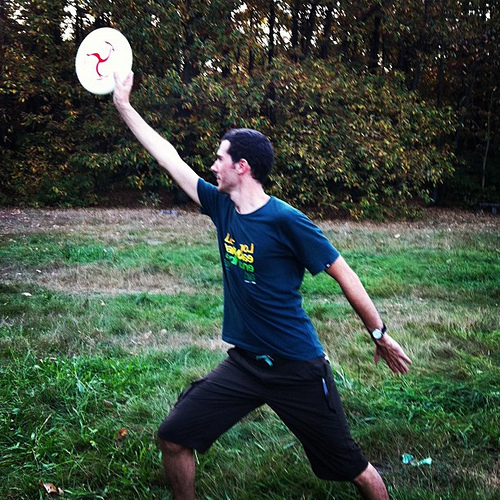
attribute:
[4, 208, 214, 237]
grass — brown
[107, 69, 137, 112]
hand — MAN